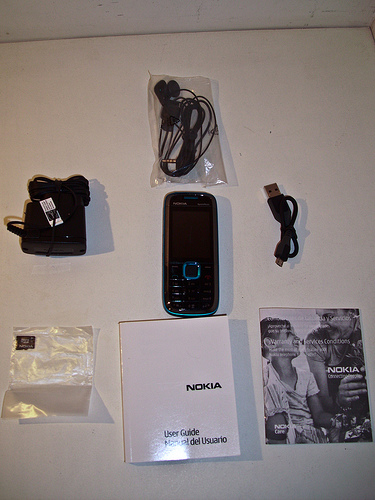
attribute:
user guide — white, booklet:
[117, 315, 242, 465]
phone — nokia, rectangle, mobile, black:
[160, 190, 220, 316]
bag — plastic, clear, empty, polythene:
[2, 325, 97, 422]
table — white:
[0, 25, 373, 495]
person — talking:
[260, 316, 321, 444]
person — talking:
[305, 308, 370, 442]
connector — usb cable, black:
[264, 182, 300, 268]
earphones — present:
[153, 78, 217, 177]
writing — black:
[164, 427, 228, 450]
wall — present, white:
[1, 0, 374, 41]